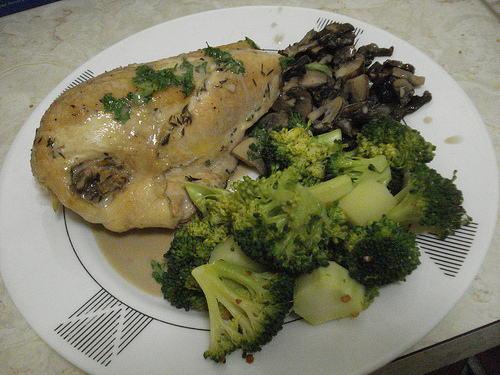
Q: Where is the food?
A: On a plate.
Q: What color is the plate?
A: White.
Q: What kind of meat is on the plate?
A: Chicken.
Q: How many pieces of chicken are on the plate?
A: 1.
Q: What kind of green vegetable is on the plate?
A: Broccoli.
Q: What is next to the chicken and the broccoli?
A: Mushrooms.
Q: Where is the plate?
A: On a table.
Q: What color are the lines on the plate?
A: Black.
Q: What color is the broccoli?
A: Green.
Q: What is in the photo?
A: Dinner.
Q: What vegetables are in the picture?
A: Mushrooms and broccoli.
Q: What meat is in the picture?
A: Chicken.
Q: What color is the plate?
A: White with black trim.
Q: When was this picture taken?
A: Dinner time.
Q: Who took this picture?
A: Maybe the chef.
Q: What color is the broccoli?
A: Green.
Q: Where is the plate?
A: On a table.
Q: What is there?
A: Food.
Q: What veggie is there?
A: Broccoli.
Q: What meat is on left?
A: Chicken.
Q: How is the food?
A: Organized.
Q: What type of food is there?
A: Dinner.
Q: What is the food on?
A: Plate.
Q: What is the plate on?
A: Table.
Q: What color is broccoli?
A: Green.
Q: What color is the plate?
A: White.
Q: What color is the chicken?
A: Golden brown.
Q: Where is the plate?
A: On the table.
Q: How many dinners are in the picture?
A: One.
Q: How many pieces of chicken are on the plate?
A: One.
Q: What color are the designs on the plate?
A: Black.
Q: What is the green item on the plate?
A: Broccoli.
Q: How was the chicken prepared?
A: Grilled.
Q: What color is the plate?
A: White and black.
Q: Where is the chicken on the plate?
A: On the top left.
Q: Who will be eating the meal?
A: People.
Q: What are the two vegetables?
A: Broccoli and mushrooms.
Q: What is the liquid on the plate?
A: Juice.